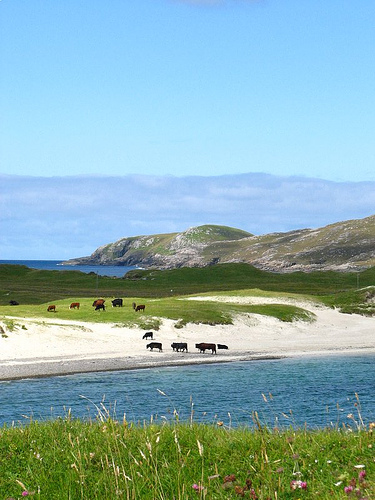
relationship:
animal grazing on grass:
[69, 302, 81, 310] [54, 294, 208, 330]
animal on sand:
[146, 342, 163, 352] [118, 347, 229, 367]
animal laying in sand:
[217, 343, 229, 349] [212, 349, 237, 359]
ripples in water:
[184, 386, 314, 406] [56, 360, 366, 445]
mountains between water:
[105, 219, 366, 275] [67, 349, 347, 412]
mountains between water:
[105, 219, 366, 275] [28, 252, 147, 284]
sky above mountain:
[11, 10, 366, 174] [29, 176, 357, 266]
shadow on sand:
[167, 345, 216, 354] [133, 349, 275, 367]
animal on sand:
[170, 338, 192, 350] [146, 349, 229, 366]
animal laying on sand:
[213, 338, 233, 350] [178, 351, 311, 362]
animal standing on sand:
[170, 342, 189, 352] [0, 314, 372, 376]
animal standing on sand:
[145, 341, 164, 352] [0, 314, 372, 376]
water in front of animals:
[0, 355, 372, 427] [145, 341, 228, 355]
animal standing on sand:
[142, 331, 152, 339] [1, 316, 373, 359]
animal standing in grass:
[132, 301, 136, 310] [0, 287, 374, 337]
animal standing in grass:
[111, 295, 124, 308] [0, 287, 374, 337]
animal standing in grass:
[91, 298, 104, 304] [0, 287, 374, 337]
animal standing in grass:
[67, 298, 81, 311] [0, 287, 374, 337]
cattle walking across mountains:
[8, 298, 228, 352] [60, 212, 373, 277]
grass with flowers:
[0, 394, 372, 498] [9, 462, 373, 497]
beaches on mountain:
[0, 297, 370, 378] [0, 213, 372, 378]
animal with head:
[69, 302, 81, 310] [67, 305, 71, 308]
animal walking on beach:
[146, 342, 163, 352] [0, 295, 374, 378]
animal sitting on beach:
[217, 343, 229, 349] [0, 295, 374, 378]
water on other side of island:
[3, 257, 146, 278] [0, 262, 372, 381]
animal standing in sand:
[142, 331, 154, 340] [0, 292, 374, 375]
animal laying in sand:
[217, 343, 229, 349] [0, 292, 374, 375]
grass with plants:
[0, 394, 372, 498] [2, 389, 371, 498]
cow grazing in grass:
[135, 304, 145, 312] [0, 288, 316, 337]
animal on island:
[146, 342, 163, 352] [0, 262, 372, 381]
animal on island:
[176, 342, 188, 352] [0, 262, 372, 381]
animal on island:
[142, 331, 154, 340] [0, 262, 372, 381]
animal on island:
[69, 302, 81, 310] [0, 262, 372, 381]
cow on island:
[133, 302, 147, 311] [0, 262, 372, 381]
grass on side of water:
[0, 411, 372, 498] [1, 348, 373, 431]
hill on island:
[144, 222, 253, 267] [56, 220, 373, 268]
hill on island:
[200, 224, 311, 266] [56, 220, 373, 268]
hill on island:
[272, 211, 373, 270] [56, 220, 373, 268]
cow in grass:
[45, 302, 58, 314] [0, 260, 371, 328]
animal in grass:
[69, 302, 81, 310] [0, 260, 371, 328]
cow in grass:
[92, 301, 106, 311] [0, 260, 371, 328]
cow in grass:
[135, 304, 145, 312] [0, 260, 371, 328]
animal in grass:
[111, 298, 123, 307] [0, 260, 371, 328]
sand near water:
[0, 291, 374, 386] [1, 348, 373, 431]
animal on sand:
[142, 331, 154, 340] [0, 291, 374, 386]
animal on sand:
[146, 342, 163, 352] [0, 291, 374, 386]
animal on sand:
[217, 343, 229, 349] [0, 291, 374, 386]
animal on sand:
[176, 342, 188, 352] [0, 291, 374, 386]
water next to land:
[3, 257, 146, 278] [0, 259, 372, 377]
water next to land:
[0, 355, 372, 427] [0, 259, 372, 377]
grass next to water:
[0, 411, 372, 498] [0, 355, 372, 427]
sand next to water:
[0, 291, 374, 386] [0, 355, 372, 427]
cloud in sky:
[0, 170, 373, 262] [0, 0, 370, 259]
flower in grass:
[220, 471, 237, 485] [0, 411, 372, 498]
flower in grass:
[296, 479, 311, 491] [0, 411, 372, 498]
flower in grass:
[191, 482, 201, 492] [0, 411, 372, 498]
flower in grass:
[341, 484, 352, 492] [0, 411, 372, 498]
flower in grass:
[357, 467, 367, 478] [0, 411, 372, 498]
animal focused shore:
[217, 343, 229, 349] [103, 319, 294, 357]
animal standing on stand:
[170, 342, 182, 352] [0, 286, 373, 378]